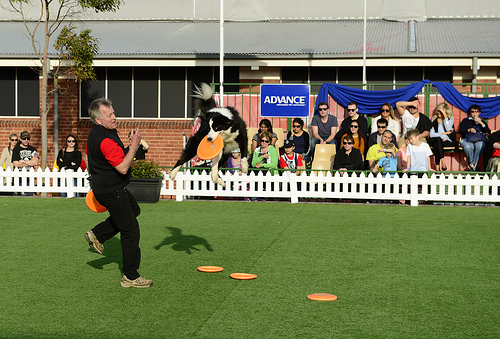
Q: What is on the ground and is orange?
A: Frisbees.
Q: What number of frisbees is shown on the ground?
A: Three.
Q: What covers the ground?
A: Grass.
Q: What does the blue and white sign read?
A: Advance.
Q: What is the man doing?
A: Throwing frisbee.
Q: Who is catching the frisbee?
A: Dog.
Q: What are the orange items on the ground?
A: Frisbees.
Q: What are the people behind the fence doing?
A: Watching.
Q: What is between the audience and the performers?
A: Fence.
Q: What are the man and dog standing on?
A: Astroturf.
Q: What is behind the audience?
A: Building.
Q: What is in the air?
A: Dog.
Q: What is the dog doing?
A: Catching a frisbee.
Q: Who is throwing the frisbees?
A: The man.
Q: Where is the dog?
A: In the air.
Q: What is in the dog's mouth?
A: A frisbee.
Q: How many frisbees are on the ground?
A: Three.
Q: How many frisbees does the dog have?
A: One.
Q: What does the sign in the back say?
A: Advance.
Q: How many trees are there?
A: One.